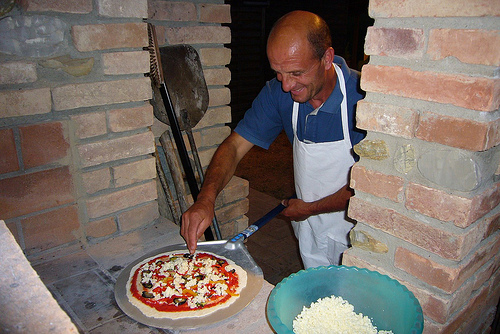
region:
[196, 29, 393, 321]
man is making pizza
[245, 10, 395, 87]
man has little hair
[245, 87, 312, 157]
man has blue shirt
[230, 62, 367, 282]
man has white apron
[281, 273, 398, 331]
mozzarella cheese in blue bowl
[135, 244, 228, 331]
pizza is on stone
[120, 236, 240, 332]
pizza stone is grey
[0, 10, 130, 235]
brick oven is tan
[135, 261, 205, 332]
red tomato sauce on pizza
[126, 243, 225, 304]
black olives on pizza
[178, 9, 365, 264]
a man wearing a white apron applying cheese to an uncooked pizza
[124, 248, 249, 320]
an uncooked pizza sitting on top of a pizza peel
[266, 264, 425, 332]
a large light blue bowl filled with mozzarella cheese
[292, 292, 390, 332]
a pile of mozzarella cheese sitting inside a bowl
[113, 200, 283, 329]
a large metal pizza peel being held by a man creating a pizza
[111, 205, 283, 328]
a large pizza peel with an uncooked pizza sitting on top of it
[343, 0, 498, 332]
a post made of brick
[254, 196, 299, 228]
a dark blue handle that is attached to a large pizza peel being held by a man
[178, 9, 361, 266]
a male pizza maker holding a handle of a pizza peel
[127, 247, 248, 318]
an uncooked pizza with vegetable toppings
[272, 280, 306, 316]
edge of a trough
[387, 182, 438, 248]
part of a pillar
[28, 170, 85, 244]
part of a wall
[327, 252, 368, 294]
part of a trough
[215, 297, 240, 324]
edge of a dish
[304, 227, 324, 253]
part of a cloth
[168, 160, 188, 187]
part of a stick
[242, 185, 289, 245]
part of a handle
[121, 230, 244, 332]
pizza ready for the oven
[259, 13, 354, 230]
man wearing a white apron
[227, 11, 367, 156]
man wearing a blue shirt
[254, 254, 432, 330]
blue bowl with scalloped edge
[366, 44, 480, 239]
red brick and mortar wall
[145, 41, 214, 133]
large spatula for taking pizza out of the oven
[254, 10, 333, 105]
man with no hair on top of head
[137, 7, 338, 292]
man putting cheese on pizza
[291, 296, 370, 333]
cheese in a bowl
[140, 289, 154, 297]
mushroom on pizza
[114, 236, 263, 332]
Uncooked pizza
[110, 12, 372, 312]
A pizza chef ready to put pizza in the oven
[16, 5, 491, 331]
Brick oven pizzeria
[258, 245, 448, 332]
Grated white cheese in a large blue bowl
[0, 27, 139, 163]
Brick wall of pizzeria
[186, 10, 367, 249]
A man wearing a blue polo and white apron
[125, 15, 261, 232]
Brick oven baking tools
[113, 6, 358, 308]
A man looking at the pizza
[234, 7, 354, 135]
Smiling face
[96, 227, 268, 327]
Thin crust pizza ready to bake